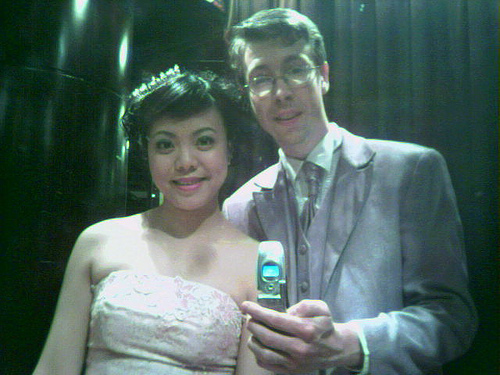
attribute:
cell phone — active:
[254, 236, 291, 311]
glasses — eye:
[243, 60, 320, 92]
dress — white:
[72, 264, 206, 362]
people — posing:
[251, 22, 428, 234]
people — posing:
[64, 69, 255, 334]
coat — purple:
[230, 131, 477, 307]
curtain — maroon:
[229, 2, 488, 264]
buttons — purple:
[291, 230, 315, 297]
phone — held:
[255, 239, 286, 314]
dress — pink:
[52, 256, 293, 373]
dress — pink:
[73, 247, 285, 373]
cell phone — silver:
[226, 217, 331, 310]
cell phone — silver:
[243, 231, 304, 360]